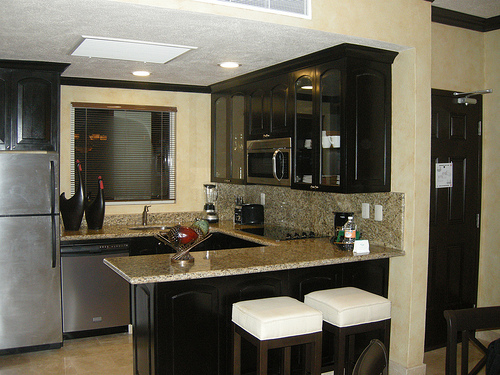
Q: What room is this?
A: Kitchen.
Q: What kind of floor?
A: Tile.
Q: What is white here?
A: Cushions.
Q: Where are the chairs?
A: At the bar.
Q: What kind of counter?
A: Marble.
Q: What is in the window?
A: Blinds.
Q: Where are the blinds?
A: In the window.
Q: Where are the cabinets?
A: On the wall.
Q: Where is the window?
A: Above the sink.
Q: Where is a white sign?
A: Door.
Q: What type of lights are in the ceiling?
A: Recessed.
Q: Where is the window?
A: Over the sink.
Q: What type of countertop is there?
A: Granite.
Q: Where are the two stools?
A: At the kitchen bar.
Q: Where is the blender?
A: To the right of the window.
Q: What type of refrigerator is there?
A: Steel.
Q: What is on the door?
A: A piece of paper.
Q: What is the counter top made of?
A: Granite.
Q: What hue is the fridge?
A: Silver.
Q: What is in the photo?
A: A fridge.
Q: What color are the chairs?
A: White.